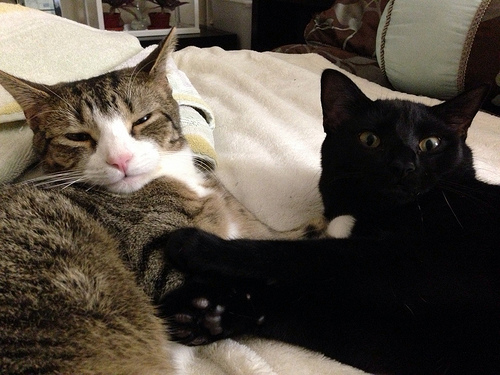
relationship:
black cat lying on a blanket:
[170, 65, 480, 365] [190, 59, 316, 166]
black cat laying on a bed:
[136, 67, 499, 374] [0, 4, 494, 353]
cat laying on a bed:
[0, 27, 230, 375] [0, 4, 494, 353]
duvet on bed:
[234, 82, 311, 207] [0, 4, 494, 353]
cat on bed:
[0, 25, 240, 372] [0, 4, 494, 353]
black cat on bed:
[136, 67, 499, 374] [0, 4, 494, 353]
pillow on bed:
[0, 3, 152, 83] [0, 4, 494, 353]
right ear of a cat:
[138, 26, 178, 75] [6, 27, 275, 370]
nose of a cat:
[106, 150, 132, 174] [0, 25, 240, 372]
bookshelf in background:
[40, 7, 372, 65] [8, 1, 371, 60]